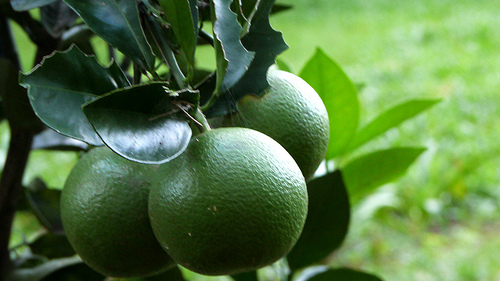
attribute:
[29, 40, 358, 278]
limes — trio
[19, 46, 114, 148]
leaf — dark green, ridged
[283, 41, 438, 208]
leaves — light green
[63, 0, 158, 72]
leaf — jagged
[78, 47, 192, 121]
leaf — light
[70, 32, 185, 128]
leaves — dark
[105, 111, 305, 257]
limes — dark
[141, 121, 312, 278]
lime — round, green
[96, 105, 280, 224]
limes — green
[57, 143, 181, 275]
orange — unripe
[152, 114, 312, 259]
orange — unripe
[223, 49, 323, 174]
orange — unripe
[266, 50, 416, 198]
leaf — dark, green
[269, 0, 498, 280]
plants — wild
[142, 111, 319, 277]
lime — round, green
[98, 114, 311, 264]
oranges — green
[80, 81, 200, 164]
leaf — dark, dark green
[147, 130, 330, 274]
lime — dark green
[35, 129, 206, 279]
lime — dark green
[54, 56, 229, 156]
leaf — dark green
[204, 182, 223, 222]
spot — brown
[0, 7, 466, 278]
tree — lime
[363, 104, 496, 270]
lawn — green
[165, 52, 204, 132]
stem — lime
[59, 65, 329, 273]
limes — green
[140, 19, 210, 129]
stem — dark green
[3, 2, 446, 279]
plant — green